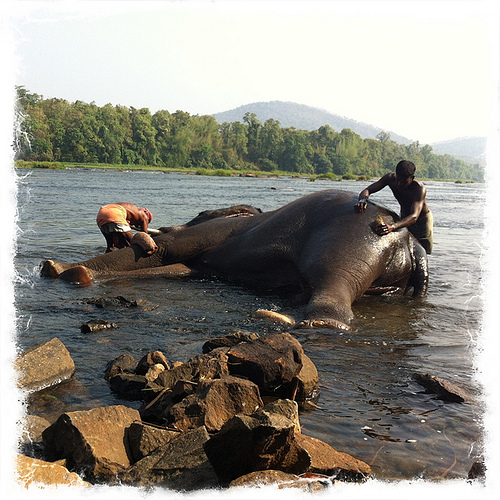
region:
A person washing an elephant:
[360, 146, 436, 261]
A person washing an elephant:
[75, 180, 156, 257]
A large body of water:
[15, 165, 480, 475]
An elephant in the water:
[42, 186, 431, 333]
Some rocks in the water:
[23, 337, 460, 492]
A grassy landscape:
[18, 159, 386, 179]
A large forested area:
[16, 87, 486, 179]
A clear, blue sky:
[15, 4, 499, 129]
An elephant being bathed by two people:
[43, 160, 448, 335]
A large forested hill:
[205, 100, 400, 138]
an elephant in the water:
[31, 65, 493, 420]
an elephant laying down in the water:
[59, 146, 491, 419]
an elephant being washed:
[70, 149, 499, 347]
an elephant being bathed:
[67, 144, 483, 357]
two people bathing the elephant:
[56, 140, 498, 420]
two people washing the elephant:
[77, 159, 467, 352]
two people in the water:
[72, 149, 497, 367]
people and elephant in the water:
[60, 145, 463, 383]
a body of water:
[351, 356, 440, 480]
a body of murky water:
[336, 347, 441, 470]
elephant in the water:
[192, 165, 385, 339]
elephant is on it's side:
[86, 168, 489, 281]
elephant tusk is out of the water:
[146, 195, 193, 249]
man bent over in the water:
[74, 177, 199, 279]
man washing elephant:
[376, 135, 450, 256]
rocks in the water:
[88, 300, 481, 453]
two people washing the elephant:
[110, 144, 446, 275]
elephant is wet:
[171, 162, 386, 338]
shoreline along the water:
[59, 150, 344, 187]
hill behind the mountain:
[189, 87, 443, 170]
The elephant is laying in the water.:
[168, 190, 382, 305]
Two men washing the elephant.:
[86, 158, 442, 279]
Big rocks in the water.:
[174, 332, 312, 469]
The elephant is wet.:
[180, 202, 390, 319]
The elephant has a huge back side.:
[356, 240, 449, 307]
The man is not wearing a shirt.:
[378, 167, 437, 218]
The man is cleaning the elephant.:
[334, 145, 449, 257]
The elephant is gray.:
[213, 198, 370, 304]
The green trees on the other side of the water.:
[72, 94, 297, 186]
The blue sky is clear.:
[166, 33, 440, 131]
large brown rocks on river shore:
[133, 329, 344, 471]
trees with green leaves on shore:
[52, 117, 306, 165]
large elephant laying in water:
[143, 164, 439, 334]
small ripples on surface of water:
[80, 172, 198, 201]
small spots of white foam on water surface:
[338, 399, 445, 450]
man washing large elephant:
[343, 137, 460, 277]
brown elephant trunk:
[131, 232, 168, 257]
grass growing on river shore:
[62, 161, 137, 174]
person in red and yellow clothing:
[79, 163, 171, 271]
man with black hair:
[368, 151, 435, 196]